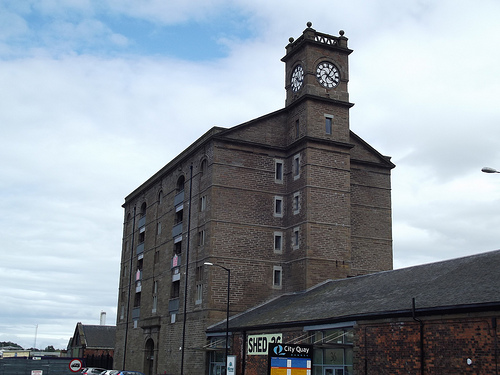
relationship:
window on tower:
[322, 113, 337, 143] [283, 23, 357, 296]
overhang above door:
[135, 315, 164, 329] [143, 338, 156, 374]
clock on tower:
[318, 57, 341, 90] [283, 23, 357, 296]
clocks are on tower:
[288, 62, 344, 95] [283, 23, 357, 296]